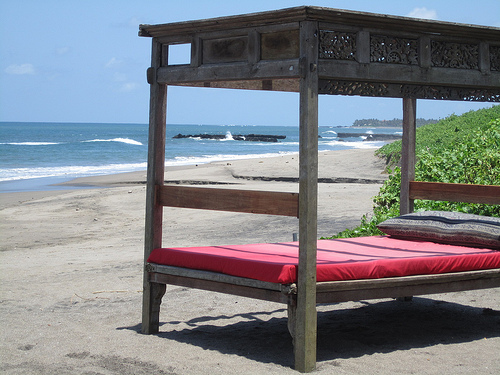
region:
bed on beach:
[153, 12, 470, 363]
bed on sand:
[145, 9, 489, 367]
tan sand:
[30, 246, 114, 311]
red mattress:
[176, 198, 473, 293]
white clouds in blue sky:
[25, 22, 66, 59]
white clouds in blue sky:
[15, 51, 63, 92]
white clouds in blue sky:
[33, 82, 74, 117]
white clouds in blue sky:
[92, 56, 123, 94]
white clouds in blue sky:
[72, 18, 106, 59]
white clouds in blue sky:
[199, 95, 231, 127]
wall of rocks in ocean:
[172, 132, 284, 141]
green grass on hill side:
[429, 123, 490, 175]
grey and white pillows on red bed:
[386, 215, 471, 242]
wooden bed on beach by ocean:
[142, 41, 482, 369]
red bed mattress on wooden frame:
[317, 235, 471, 288]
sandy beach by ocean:
[22, 176, 81, 210]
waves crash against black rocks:
[222, 132, 234, 142]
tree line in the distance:
[354, 118, 401, 126]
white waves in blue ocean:
[101, 137, 140, 152]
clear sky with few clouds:
[9, 59, 67, 109]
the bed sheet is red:
[154, 202, 453, 307]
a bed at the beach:
[111, 8, 431, 373]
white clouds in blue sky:
[18, 40, 49, 75]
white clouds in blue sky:
[50, 42, 112, 92]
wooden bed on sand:
[135, 15, 465, 365]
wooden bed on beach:
[105, 10, 495, 346]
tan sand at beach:
[20, 196, 85, 249]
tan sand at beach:
[33, 265, 98, 315]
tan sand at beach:
[43, 315, 109, 356]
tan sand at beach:
[89, 193, 122, 247]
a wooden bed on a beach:
[142, 9, 497, 364]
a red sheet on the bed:
[146, 241, 491, 279]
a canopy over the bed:
[157, 4, 497, 99]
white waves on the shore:
[16, 161, 118, 191]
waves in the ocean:
[26, 123, 134, 148]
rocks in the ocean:
[183, 128, 277, 143]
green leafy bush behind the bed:
[390, 120, 482, 215]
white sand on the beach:
[24, 182, 120, 299]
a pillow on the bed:
[371, 206, 498, 241]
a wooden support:
[152, 182, 306, 216]